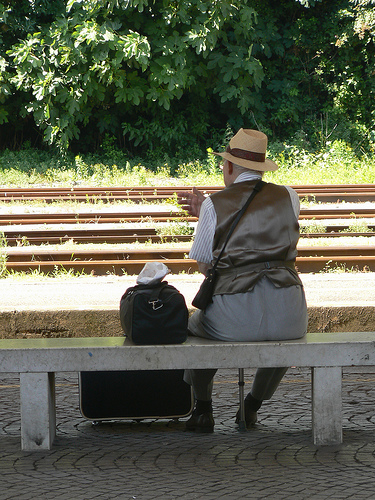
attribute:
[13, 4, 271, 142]
tree — growing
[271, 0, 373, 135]
tree — growing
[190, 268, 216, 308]
bag — black, shoulder bag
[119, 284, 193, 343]
bag — black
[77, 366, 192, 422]
bag — black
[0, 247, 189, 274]
track — metal, rail road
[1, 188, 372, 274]
tracks — rusted, colored, train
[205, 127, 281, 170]
hat — tan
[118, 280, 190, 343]
bag — black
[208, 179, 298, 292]
vest — shiny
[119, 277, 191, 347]
suitcase — black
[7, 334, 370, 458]
bench — white, granite, concrete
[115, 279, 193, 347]
duffle bag — black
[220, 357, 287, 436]
cane — silver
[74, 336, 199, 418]
suitcase — black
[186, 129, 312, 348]
person — old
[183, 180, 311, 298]
shirt — striped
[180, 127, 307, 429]
man — sitting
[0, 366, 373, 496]
walkway — concrete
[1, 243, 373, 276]
track — train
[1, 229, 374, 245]
track — train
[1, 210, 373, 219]
track — train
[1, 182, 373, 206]
track — train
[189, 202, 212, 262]
dress shirt — white, striped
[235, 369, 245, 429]
cane — bottom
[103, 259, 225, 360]
bag — black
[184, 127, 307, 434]
person — old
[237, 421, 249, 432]
tip — grey, rubber